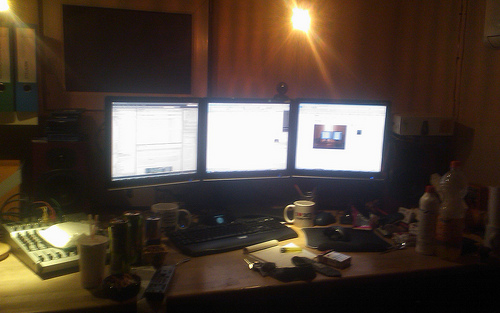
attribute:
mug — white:
[283, 200, 319, 230]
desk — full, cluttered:
[2, 197, 499, 312]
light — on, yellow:
[279, 2, 323, 43]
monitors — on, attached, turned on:
[99, 95, 399, 192]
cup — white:
[77, 232, 110, 293]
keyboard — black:
[165, 215, 297, 256]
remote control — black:
[146, 261, 174, 301]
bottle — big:
[439, 158, 469, 263]